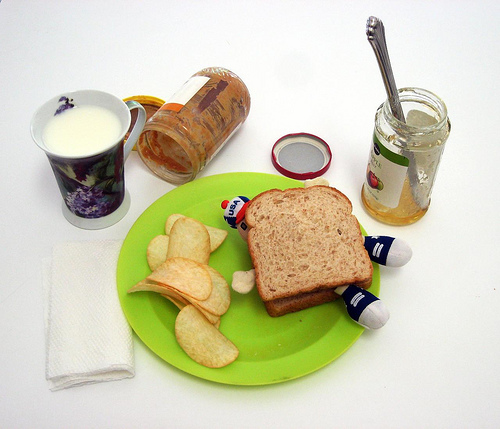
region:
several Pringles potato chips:
[132, 220, 236, 366]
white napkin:
[47, 238, 127, 379]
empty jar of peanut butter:
[128, 67, 251, 179]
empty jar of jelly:
[362, 90, 447, 224]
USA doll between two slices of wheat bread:
[221, 180, 411, 332]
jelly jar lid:
[273, 133, 331, 175]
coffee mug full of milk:
[29, 92, 143, 227]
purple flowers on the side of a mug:
[66, 185, 107, 213]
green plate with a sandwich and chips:
[112, 175, 377, 387]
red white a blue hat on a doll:
[217, 197, 249, 224]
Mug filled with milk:
[30, 88, 143, 228]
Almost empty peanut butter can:
[140, 65, 247, 182]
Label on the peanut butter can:
[155, 71, 207, 108]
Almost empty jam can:
[360, 85, 446, 221]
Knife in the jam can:
[365, 12, 427, 207]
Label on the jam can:
[360, 133, 408, 206]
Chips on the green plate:
[130, 210, 241, 369]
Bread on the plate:
[245, 185, 373, 317]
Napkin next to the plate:
[45, 228, 132, 389]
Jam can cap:
[271, 129, 331, 179]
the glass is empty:
[165, 66, 342, 316]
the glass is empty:
[125, 20, 291, 290]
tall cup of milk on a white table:
[21, 71, 145, 229]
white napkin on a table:
[32, 238, 137, 392]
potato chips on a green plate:
[146, 212, 244, 368]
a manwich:
[218, 182, 410, 329]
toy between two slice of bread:
[216, 189, 417, 329]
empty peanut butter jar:
[135, 58, 252, 182]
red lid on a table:
[264, 126, 341, 178]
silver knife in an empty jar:
[343, 9, 457, 225]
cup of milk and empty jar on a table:
[30, 61, 255, 223]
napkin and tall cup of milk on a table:
[22, 88, 143, 393]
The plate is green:
[239, 313, 351, 407]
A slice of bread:
[249, 182, 371, 300]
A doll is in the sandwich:
[222, 177, 417, 333]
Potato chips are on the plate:
[139, 210, 232, 365]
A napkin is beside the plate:
[41, 235, 136, 390]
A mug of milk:
[29, 80, 149, 232]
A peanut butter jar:
[138, 60, 256, 181]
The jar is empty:
[140, 122, 205, 178]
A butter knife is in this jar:
[354, 11, 461, 226]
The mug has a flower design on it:
[48, 161, 127, 218]